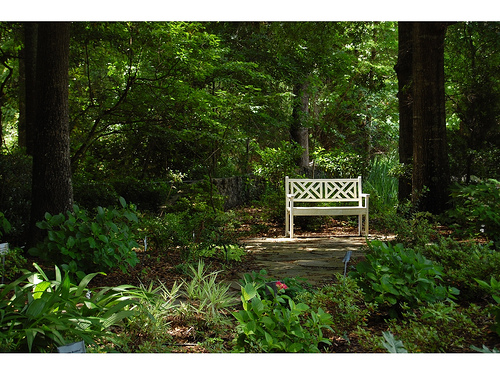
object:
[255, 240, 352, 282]
shadow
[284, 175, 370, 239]
bench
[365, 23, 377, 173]
tree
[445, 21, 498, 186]
tree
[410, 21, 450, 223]
brown tree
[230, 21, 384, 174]
trees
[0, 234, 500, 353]
plants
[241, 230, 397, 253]
light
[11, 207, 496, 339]
ground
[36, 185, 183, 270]
bush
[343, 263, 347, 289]
stem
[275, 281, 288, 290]
pink flower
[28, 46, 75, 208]
tree trunk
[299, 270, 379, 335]
weeds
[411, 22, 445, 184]
tree trunk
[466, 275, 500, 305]
leaves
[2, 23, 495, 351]
woods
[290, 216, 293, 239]
legs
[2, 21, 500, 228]
trees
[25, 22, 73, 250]
tree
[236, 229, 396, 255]
spot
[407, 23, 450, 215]
tree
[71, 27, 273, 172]
branches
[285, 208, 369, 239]
stand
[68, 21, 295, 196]
tree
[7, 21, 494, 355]
forest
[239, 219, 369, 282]
dirt